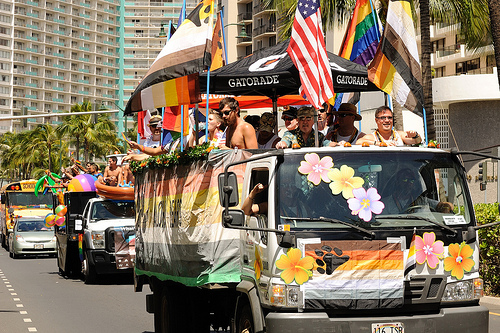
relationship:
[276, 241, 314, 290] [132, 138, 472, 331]
flower on truck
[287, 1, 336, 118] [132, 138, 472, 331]
flag on truck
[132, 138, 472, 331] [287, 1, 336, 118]
truck with flag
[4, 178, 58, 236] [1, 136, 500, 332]
school bus down street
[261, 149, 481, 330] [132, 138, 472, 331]
front of truck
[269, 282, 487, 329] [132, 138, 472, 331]
grill on truck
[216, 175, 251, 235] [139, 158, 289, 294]
mirrors on side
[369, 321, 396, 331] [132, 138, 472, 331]
license plate on truck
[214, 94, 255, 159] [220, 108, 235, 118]
man wearing glasses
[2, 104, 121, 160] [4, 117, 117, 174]
cluster of trees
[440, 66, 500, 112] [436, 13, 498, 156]
balcony of building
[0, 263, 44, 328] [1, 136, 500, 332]
lines on street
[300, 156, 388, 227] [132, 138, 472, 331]
flowers on truck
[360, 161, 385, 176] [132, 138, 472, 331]
mirror on truck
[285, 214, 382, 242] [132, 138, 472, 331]
wiper on truck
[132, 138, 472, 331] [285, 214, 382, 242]
truck has wiper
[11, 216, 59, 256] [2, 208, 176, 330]
car on road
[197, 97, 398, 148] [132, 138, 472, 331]
people on truck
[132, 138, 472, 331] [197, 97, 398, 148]
truck full of people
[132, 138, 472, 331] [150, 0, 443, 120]
truck with flags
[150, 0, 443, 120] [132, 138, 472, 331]
flags on truck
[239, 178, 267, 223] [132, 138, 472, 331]
arm outside of truck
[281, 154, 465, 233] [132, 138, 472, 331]
windshield of truck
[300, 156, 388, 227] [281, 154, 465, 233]
flowers on windshield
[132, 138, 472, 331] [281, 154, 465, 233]
truck has windshield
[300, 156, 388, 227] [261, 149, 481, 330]
flowers on front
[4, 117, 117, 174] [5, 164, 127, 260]
trees beside cars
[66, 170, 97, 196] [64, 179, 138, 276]
beach ball on truck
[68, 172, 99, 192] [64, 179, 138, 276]
beach ball on truck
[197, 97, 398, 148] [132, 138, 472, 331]
people on trucks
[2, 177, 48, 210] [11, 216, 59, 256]
bus follows car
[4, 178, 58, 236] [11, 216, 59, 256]
school bus follows car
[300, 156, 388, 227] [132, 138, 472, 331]
window of truck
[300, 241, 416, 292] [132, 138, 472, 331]
banner on truck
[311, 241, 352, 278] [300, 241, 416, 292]
paw print on banner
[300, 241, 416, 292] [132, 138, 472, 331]
banner in front of truck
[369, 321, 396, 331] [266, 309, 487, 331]
license plate on bumper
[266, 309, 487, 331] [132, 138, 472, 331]
bumper of truck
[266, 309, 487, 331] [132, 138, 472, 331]
bumper on truck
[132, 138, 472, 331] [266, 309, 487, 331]
truck has bumper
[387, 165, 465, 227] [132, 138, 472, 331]
man driving truck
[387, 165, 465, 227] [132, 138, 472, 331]
man in truck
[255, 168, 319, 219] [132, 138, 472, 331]
passenger inside truck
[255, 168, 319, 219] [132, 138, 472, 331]
passenger sitting in truck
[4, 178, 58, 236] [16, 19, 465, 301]
school bus in parade